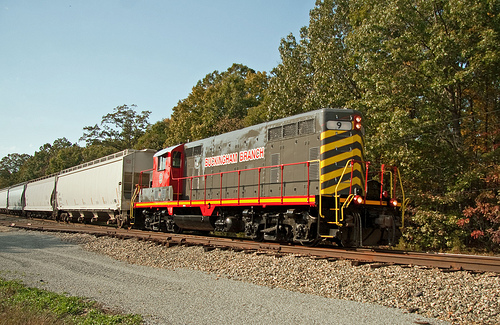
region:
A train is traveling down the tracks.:
[0, 105, 390, 236]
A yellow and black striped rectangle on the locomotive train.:
[147, 101, 374, 212]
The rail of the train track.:
[392, 253, 497, 278]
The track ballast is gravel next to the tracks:
[230, 252, 499, 289]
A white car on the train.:
[56, 145, 146, 223]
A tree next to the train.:
[405, 0, 498, 232]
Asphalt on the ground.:
[117, 281, 244, 313]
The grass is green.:
[3, 286, 73, 317]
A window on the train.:
[151, 151, 168, 168]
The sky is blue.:
[5, 9, 193, 76]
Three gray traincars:
[8, 156, 140, 226]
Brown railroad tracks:
[78, 219, 345, 274]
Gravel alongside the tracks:
[47, 232, 270, 282]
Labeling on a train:
[199, 146, 283, 167]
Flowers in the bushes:
[453, 160, 498, 247]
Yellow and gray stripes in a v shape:
[329, 107, 370, 199]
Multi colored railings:
[333, 158, 410, 234]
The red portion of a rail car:
[155, 148, 187, 200]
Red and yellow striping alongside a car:
[137, 200, 317, 212]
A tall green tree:
[101, 103, 153, 146]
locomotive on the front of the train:
[131, 108, 415, 241]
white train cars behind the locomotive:
[0, 149, 154, 231]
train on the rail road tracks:
[1, 110, 415, 257]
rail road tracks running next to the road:
[0, 200, 499, 281]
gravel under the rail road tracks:
[2, 215, 498, 320]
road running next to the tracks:
[2, 225, 450, 323]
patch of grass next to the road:
[0, 280, 142, 322]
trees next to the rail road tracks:
[0, 0, 498, 256]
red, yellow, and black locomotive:
[130, 97, 412, 246]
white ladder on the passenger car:
[119, 147, 136, 224]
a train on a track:
[5, 109, 421, 242]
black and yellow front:
[319, 131, 366, 208]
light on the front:
[349, 114, 366, 134]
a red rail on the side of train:
[172, 173, 313, 213]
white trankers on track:
[9, 144, 146, 220]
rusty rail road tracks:
[82, 239, 480, 277]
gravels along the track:
[182, 263, 446, 300]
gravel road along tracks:
[48, 280, 355, 323]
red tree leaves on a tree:
[456, 114, 495, 248]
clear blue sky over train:
[10, 10, 263, 125]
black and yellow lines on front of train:
[325, 134, 346, 182]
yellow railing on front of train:
[330, 160, 351, 224]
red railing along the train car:
[191, 172, 313, 192]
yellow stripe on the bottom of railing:
[184, 199, 209, 205]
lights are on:
[348, 189, 405, 210]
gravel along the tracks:
[295, 263, 343, 295]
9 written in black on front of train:
[331, 121, 349, 128]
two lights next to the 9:
[353, 109, 364, 134]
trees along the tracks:
[215, 67, 330, 119]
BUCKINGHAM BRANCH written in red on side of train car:
[202, 141, 266, 167]